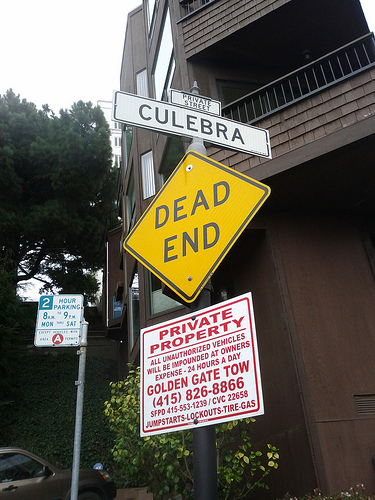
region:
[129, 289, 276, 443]
white square sign with red writing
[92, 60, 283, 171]
white and black street sign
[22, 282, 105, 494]
parking hours sign on a post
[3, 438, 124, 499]
brown parked sedan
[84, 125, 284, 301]
yellow and black Dead End sign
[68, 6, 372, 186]
brown exterior of building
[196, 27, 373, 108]
brown balcony railing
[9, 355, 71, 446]
wall with thick green ivy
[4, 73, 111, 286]
green leaves on a tree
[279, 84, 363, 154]
brown wooden wall tiles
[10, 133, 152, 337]
the tree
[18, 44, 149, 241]
the tree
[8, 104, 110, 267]
the tree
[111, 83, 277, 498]
four signs on a black pole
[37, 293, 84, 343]
blue and white parking sign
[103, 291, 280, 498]
green bush behind a street sign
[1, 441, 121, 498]
brown parked vehicle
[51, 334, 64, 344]
red A sticker on a parking sign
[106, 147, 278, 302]
diamond shaped sign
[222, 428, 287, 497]
a bunch of green bush leaves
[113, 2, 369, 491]
tall brown building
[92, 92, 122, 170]
tall white building with lots of windows on it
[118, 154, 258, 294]
a black and yellow sign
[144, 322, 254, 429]
a red and white parking sign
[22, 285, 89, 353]
a green and white sign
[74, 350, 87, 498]
a long metal pole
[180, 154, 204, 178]
a metal bolt in the sign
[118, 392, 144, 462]
a green shrub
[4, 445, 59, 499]
a gold vehicle parkes nearby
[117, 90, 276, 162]
a black and white street sign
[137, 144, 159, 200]
a rectangular window in the building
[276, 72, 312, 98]
black metal railing on the building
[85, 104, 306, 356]
a yellow sign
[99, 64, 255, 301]
a yellow sign